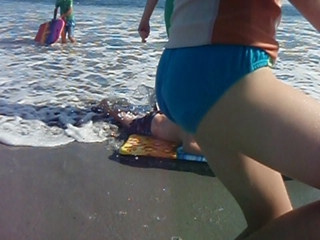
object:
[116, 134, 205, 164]
floatation device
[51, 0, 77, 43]
man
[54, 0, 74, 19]
green shirt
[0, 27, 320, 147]
foam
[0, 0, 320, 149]
water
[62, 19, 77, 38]
swimming trunks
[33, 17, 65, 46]
board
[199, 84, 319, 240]
leg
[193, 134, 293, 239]
leg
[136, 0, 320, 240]
surfer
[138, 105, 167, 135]
butt